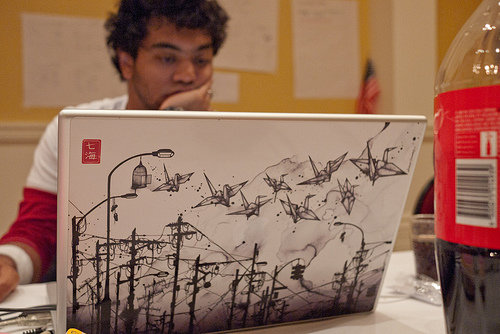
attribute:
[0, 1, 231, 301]
man — relaxed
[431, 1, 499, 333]
bottle — coke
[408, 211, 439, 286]
glass — dark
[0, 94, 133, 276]
shirt — white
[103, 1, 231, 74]
hair — black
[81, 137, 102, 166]
symbol — red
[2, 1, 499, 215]
wall — yellow